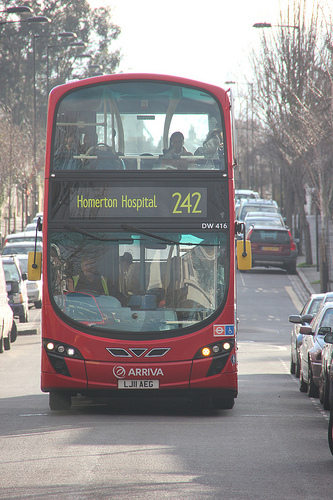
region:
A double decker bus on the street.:
[27, 115, 241, 398]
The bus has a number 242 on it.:
[167, 169, 214, 218]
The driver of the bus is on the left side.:
[55, 245, 118, 320]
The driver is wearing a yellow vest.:
[64, 272, 114, 301]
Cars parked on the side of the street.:
[270, 292, 331, 389]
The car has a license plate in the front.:
[112, 364, 171, 396]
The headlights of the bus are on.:
[44, 332, 230, 369]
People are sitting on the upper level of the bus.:
[140, 117, 218, 171]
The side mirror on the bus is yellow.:
[236, 237, 255, 277]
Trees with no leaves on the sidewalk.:
[269, 67, 332, 240]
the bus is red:
[38, 69, 238, 414]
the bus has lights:
[44, 340, 230, 359]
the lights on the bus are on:
[44, 338, 230, 365]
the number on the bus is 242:
[164, 189, 206, 219]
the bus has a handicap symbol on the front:
[223, 323, 237, 337]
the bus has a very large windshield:
[46, 222, 233, 340]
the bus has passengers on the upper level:
[57, 119, 216, 174]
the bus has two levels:
[38, 73, 240, 412]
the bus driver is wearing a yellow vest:
[69, 274, 111, 301]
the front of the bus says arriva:
[126, 364, 165, 379]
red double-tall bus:
[40, 72, 238, 414]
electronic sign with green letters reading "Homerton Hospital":
[70, 188, 207, 218]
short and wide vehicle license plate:
[117, 378, 158, 388]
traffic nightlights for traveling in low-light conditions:
[196, 337, 233, 356]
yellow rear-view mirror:
[236, 240, 250, 271]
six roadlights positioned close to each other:
[1, 5, 104, 71]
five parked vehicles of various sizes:
[234, 187, 298, 273]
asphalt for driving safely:
[1, 416, 327, 499]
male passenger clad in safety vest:
[66, 254, 123, 305]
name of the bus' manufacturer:
[112, 364, 164, 378]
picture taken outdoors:
[21, 182, 309, 495]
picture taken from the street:
[4, 387, 308, 494]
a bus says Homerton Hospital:
[67, 178, 179, 245]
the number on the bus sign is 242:
[171, 191, 275, 260]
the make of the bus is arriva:
[40, 189, 286, 460]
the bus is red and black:
[51, 218, 301, 420]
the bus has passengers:
[97, 237, 230, 349]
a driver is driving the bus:
[55, 228, 191, 404]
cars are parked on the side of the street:
[261, 247, 330, 413]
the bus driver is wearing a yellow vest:
[70, 266, 199, 340]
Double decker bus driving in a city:
[19, 65, 249, 456]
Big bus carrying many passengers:
[23, 48, 246, 439]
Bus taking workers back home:
[22, 64, 249, 412]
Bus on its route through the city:
[20, 54, 250, 411]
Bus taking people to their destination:
[21, 53, 247, 431]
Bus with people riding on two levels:
[19, 68, 253, 434]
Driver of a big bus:
[56, 248, 110, 306]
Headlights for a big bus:
[192, 337, 232, 357]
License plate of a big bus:
[108, 373, 161, 390]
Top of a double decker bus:
[41, 59, 238, 182]